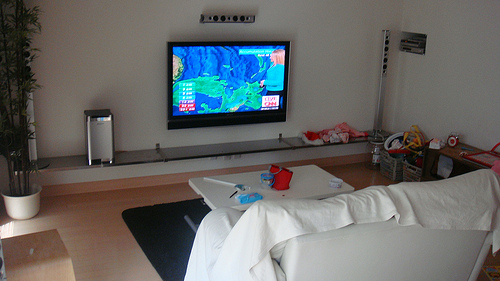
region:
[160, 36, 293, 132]
a flat screen tv on the wall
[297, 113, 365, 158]
a pile of cloths on the shelf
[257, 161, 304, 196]
a red bag on the table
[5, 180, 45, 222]
a wite pot for a plant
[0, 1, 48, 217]
a plant near the wall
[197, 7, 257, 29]
the speaker above the tv on the wall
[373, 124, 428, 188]
a pile of toys in the corner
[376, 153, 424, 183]
clear buckets for the toys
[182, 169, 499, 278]
a white cover on the couch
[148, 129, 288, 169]
the shelf on the wall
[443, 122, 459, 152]
A red alarm clock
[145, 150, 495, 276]
A white recliner chair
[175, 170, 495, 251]
A white blanket on top of a white chair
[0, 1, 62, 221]
A very tall potted plant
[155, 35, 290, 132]
A flat screen tv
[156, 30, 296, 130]
A tv mounted to the wall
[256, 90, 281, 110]
A 'CNN' sign on a tv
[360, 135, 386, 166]
A clear jar on the floor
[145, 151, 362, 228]
A white table on a black rug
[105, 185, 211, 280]
A black rug on a wooden floor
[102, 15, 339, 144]
television on white wall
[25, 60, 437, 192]
wall length shelf below television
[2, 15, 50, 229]
plant in white pot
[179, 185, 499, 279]
white chair with white cover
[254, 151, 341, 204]
red bag on white table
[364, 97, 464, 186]
cartons with stuff against the wall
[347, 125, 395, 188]
glass jar on the floor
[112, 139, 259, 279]
black rug on wood floor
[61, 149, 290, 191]
wood trim on white wall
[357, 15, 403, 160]
tall speaker on shelf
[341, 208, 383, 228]
part of a towel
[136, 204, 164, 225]
part of a carpet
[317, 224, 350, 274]
part of a chair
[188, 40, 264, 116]
part of a screen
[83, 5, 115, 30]
part of a wheel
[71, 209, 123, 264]
part of a floor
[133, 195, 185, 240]
part of a carpet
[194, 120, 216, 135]
edge of a television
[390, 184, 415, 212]
part of a towel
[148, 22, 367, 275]
An office in a home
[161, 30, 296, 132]
A flat screen monitor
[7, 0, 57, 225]
A tall plant in a planter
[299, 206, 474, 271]
A blanket draped over a chair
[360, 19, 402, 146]
A glass and liquid barometer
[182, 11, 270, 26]
Small speaker mounted on a wall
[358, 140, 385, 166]
A glass jar with a lid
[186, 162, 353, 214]
A white hostipal type tray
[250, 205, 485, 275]
The chair and the blanket are white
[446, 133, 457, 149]
A small red alarm clock